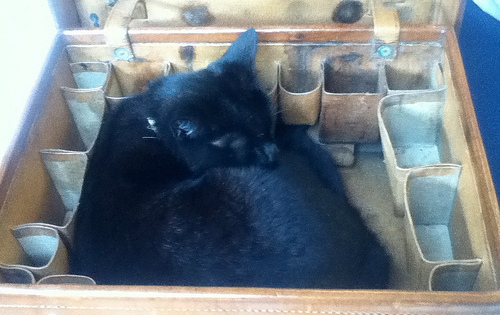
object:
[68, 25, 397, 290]
cat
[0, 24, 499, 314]
container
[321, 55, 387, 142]
divider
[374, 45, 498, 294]
row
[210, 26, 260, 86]
ear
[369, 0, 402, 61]
latch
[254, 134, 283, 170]
nose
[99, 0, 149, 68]
hinge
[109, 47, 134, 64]
attachment